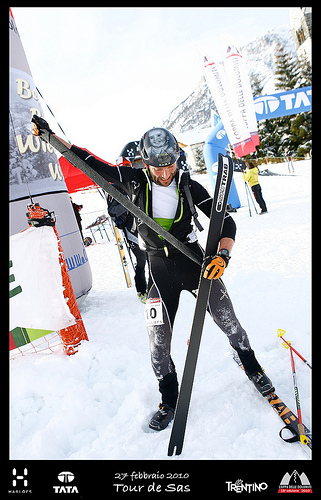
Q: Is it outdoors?
A: Yes, it is outdoors.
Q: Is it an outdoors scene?
A: Yes, it is outdoors.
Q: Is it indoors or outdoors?
A: It is outdoors.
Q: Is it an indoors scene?
A: No, it is outdoors.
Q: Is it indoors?
A: No, it is outdoors.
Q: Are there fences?
A: No, there are no fences.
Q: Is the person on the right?
A: Yes, the person is on the right of the image.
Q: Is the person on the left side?
A: No, the person is on the right of the image.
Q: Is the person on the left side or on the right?
A: The person is on the right of the image.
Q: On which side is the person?
A: The person is on the right of the image.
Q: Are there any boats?
A: No, there are no boats.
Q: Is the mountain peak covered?
A: Yes, the mountain peak is covered.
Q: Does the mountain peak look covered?
A: Yes, the mountain peak is covered.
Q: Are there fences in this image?
A: No, there are no fences.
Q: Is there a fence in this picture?
A: No, there are no fences.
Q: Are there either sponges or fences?
A: No, there are no fences or sponges.